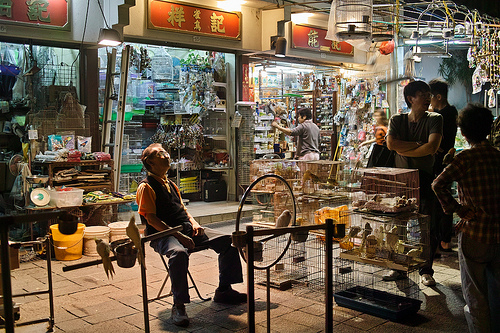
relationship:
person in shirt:
[439, 152, 492, 254] [436, 156, 497, 250]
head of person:
[140, 137, 169, 171] [138, 139, 250, 312]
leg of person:
[160, 234, 191, 302] [133, 141, 263, 330]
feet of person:
[163, 281, 265, 330] [133, 141, 263, 330]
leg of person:
[167, 237, 248, 306] [133, 141, 263, 330]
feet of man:
[170, 304, 190, 326] [135, 142, 247, 325]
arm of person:
[135, 184, 179, 237] [133, 141, 263, 330]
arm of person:
[130, 190, 180, 243] [133, 141, 263, 330]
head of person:
[140, 142, 172, 169] [129, 145, 260, 324]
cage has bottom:
[334, 265, 424, 315] [330, 290, 410, 314]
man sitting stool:
[123, 130, 257, 328] [146, 249, 208, 302]